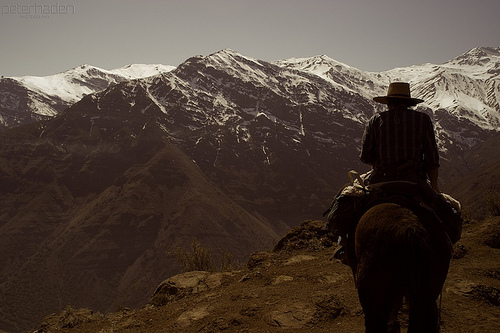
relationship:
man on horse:
[348, 67, 453, 181] [313, 175, 483, 328]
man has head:
[348, 67, 453, 181] [357, 67, 441, 122]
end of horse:
[358, 210, 420, 302] [313, 175, 483, 328]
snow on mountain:
[304, 44, 343, 63] [243, 58, 341, 108]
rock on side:
[209, 244, 256, 272] [192, 238, 252, 278]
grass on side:
[200, 272, 235, 333] [192, 238, 252, 278]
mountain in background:
[243, 58, 341, 108] [62, 30, 463, 288]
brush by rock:
[190, 223, 240, 259] [209, 244, 256, 272]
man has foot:
[348, 67, 453, 181] [322, 234, 354, 267]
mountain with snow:
[243, 58, 341, 108] [304, 44, 343, 63]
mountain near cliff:
[243, 58, 341, 108] [208, 222, 302, 296]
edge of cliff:
[233, 252, 282, 294] [208, 222, 302, 296]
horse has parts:
[313, 175, 483, 328] [399, 287, 443, 314]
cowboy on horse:
[348, 67, 453, 181] [313, 175, 483, 328]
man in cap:
[348, 67, 453, 181] [372, 81, 425, 105]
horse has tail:
[313, 175, 483, 328] [369, 267, 455, 327]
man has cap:
[355, 80, 445, 188] [372, 81, 425, 105]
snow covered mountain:
[304, 44, 343, 63] [243, 58, 341, 108]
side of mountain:
[192, 238, 252, 278] [243, 58, 341, 108]